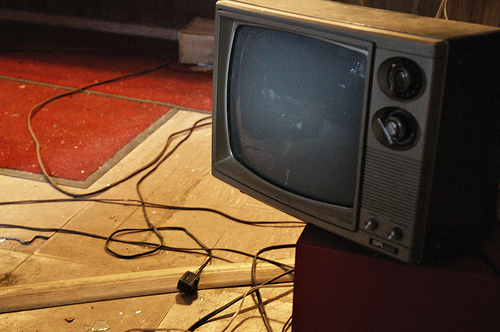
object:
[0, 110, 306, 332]
floor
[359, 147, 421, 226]
speaker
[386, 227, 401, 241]
dials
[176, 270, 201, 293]
plug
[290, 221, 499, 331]
stand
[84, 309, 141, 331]
glass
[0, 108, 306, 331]
wood flooring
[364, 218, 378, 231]
dial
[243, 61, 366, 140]
reflection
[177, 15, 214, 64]
box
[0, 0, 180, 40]
shelf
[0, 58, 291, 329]
brown cord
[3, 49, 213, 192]
carpet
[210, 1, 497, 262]
television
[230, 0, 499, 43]
dust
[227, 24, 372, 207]
monitor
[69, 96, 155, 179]
trim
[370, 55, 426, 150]
knobs